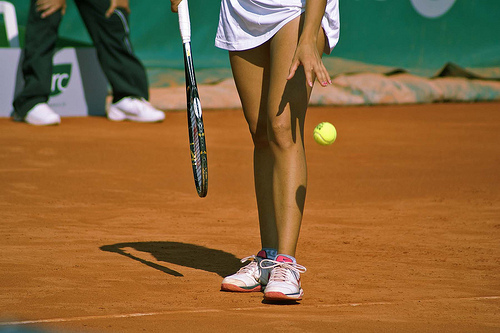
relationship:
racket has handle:
[175, 0, 209, 199] [176, 1, 191, 44]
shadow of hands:
[275, 66, 311, 151] [283, 46, 337, 88]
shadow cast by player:
[98, 240, 249, 278] [167, 2, 343, 303]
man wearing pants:
[11, 0, 166, 127] [10, 0, 149, 120]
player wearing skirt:
[171, 0, 342, 303] [207, 0, 347, 60]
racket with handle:
[175, 0, 209, 199] [173, 6, 193, 43]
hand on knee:
[97, 4, 140, 19] [93, 4, 137, 39]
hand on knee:
[34, 2, 72, 16] [25, 5, 75, 37]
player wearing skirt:
[171, 0, 342, 303] [212, 0, 340, 52]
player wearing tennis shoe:
[171, 0, 342, 303] [264, 251, 304, 303]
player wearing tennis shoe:
[171, 0, 342, 303] [221, 251, 268, 297]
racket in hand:
[175, 0, 210, 198] [170, 0, 181, 12]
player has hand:
[171, 0, 342, 303] [170, 0, 181, 12]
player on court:
[171, 0, 342, 303] [0, 92, 499, 331]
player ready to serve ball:
[171, 6, 373, 313] [311, 116, 345, 154]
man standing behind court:
[11, 0, 166, 125] [0, 92, 500, 333]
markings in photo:
[14, 288, 496, 321] [4, 9, 489, 325]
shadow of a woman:
[92, 227, 240, 293] [209, 2, 362, 319]